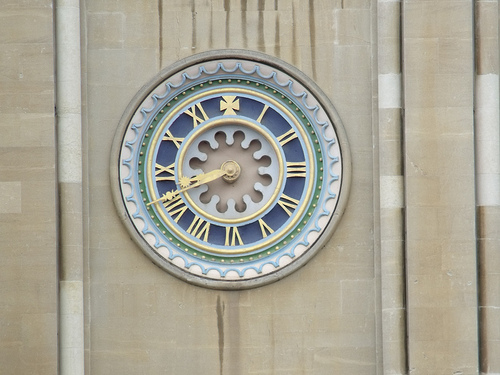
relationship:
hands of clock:
[143, 171, 223, 206] [113, 59, 345, 281]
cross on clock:
[218, 93, 241, 115] [106, 42, 356, 292]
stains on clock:
[153, 0, 330, 86] [106, 42, 356, 292]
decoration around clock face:
[123, 59, 345, 278] [149, 86, 313, 258]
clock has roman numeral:
[100, 58, 368, 290] [176, 89, 215, 135]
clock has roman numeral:
[100, 58, 368, 290] [248, 87, 284, 134]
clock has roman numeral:
[100, 58, 368, 290] [262, 117, 310, 154]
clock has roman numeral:
[100, 58, 368, 290] [270, 147, 316, 186]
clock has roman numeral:
[100, 58, 368, 290] [269, 190, 309, 223]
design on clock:
[118, 60, 341, 278] [106, 42, 356, 292]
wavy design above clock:
[142, 0, 329, 72] [106, 42, 356, 292]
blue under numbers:
[146, 94, 308, 246] [149, 90, 311, 242]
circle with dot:
[104, 45, 355, 291] [242, 77, 250, 85]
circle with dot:
[104, 45, 355, 291] [310, 128, 315, 135]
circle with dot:
[104, 45, 355, 291] [315, 193, 320, 199]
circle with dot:
[104, 45, 355, 291] [272, 244, 282, 251]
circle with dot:
[104, 45, 355, 291] [152, 219, 162, 229]